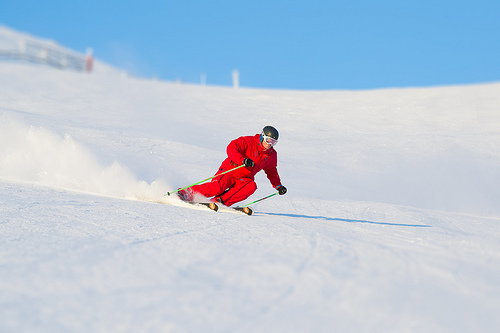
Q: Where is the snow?
A: On ground.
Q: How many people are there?
A: One.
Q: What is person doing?
A: Skiing.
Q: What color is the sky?
A: Blue.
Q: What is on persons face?
A: Gogg!es.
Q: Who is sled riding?
A: No one.